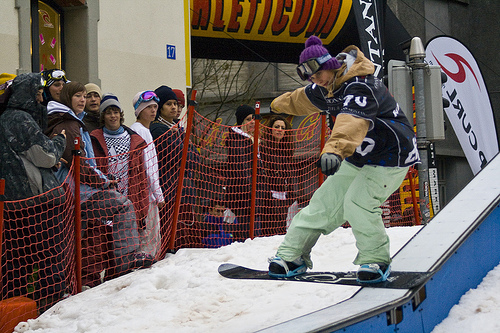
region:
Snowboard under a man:
[216, 254, 442, 301]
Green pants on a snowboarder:
[303, 149, 401, 281]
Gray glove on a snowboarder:
[306, 143, 347, 173]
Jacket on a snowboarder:
[281, 81, 428, 168]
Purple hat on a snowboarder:
[283, 20, 354, 99]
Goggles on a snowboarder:
[288, 50, 351, 82]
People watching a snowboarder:
[31, 78, 249, 276]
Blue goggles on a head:
[136, 91, 171, 128]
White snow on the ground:
[179, 237, 287, 325]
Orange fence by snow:
[132, 108, 328, 249]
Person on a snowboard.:
[188, 42, 451, 297]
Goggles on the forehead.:
[279, 50, 330, 78]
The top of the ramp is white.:
[398, 162, 496, 274]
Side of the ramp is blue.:
[422, 220, 495, 325]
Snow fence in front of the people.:
[0, 106, 384, 318]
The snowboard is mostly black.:
[216, 250, 431, 303]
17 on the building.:
[154, 35, 189, 67]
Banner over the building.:
[188, 0, 373, 62]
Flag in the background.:
[418, 20, 498, 180]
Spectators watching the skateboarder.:
[6, 70, 299, 238]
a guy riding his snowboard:
[210, 32, 427, 293]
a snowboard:
[214, 249, 434, 292]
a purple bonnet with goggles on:
[288, 33, 342, 78]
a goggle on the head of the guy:
[292, 57, 323, 78]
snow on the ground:
[130, 286, 212, 324]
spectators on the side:
[3, 70, 185, 177]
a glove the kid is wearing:
[313, 141, 344, 178]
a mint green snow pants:
[281, 156, 418, 276]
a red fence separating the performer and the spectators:
[120, 110, 258, 240]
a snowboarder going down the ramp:
[225, 35, 497, 302]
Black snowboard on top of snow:
[212, 260, 405, 288]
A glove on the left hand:
[322, 154, 341, 175]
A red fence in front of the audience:
[175, 147, 274, 202]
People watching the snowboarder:
[8, 83, 183, 247]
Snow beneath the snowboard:
[158, 281, 235, 322]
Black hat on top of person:
[233, 105, 250, 124]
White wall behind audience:
[109, 16, 149, 73]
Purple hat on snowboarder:
[300, 43, 332, 63]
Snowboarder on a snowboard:
[263, 50, 403, 287]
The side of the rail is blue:
[444, 263, 469, 288]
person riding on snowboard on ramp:
[203, 34, 463, 316]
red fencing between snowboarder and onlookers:
[107, 16, 351, 259]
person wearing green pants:
[238, 21, 440, 229]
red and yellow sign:
[198, 5, 344, 43]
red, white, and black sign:
[422, 41, 495, 166]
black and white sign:
[339, 1, 404, 71]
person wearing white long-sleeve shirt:
[122, 89, 184, 272]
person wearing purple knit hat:
[264, 20, 427, 244]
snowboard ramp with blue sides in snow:
[177, 209, 498, 331]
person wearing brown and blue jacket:
[32, 68, 135, 231]